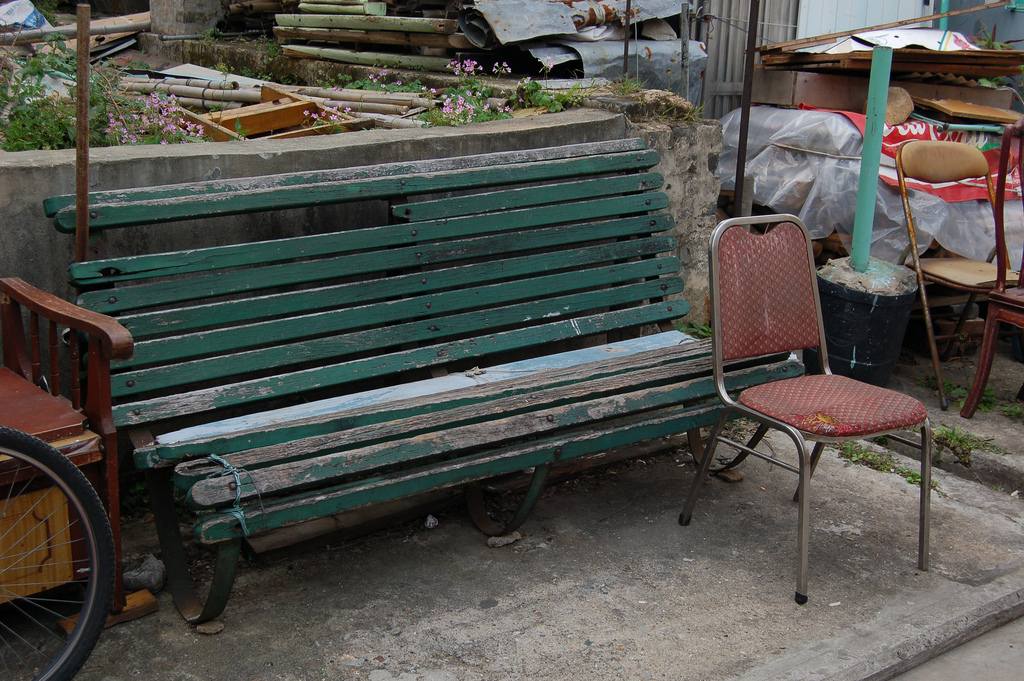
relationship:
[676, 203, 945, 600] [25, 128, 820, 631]
chair in front of bench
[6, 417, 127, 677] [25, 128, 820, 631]
tire near bench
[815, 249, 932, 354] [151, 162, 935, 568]
bucket near bench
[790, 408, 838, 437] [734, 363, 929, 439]
tear in seat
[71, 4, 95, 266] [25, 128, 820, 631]
pole near bench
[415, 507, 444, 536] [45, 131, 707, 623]
crumpled paper under bench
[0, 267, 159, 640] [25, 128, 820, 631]
chair near bench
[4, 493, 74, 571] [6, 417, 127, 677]
spokes of tire